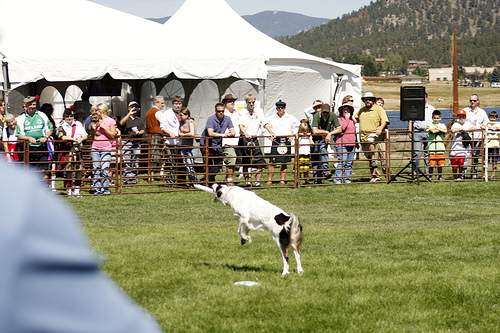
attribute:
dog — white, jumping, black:
[224, 186, 302, 262]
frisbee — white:
[195, 184, 219, 194]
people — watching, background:
[55, 91, 203, 125]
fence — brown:
[111, 141, 164, 198]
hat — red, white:
[272, 97, 281, 107]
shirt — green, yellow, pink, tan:
[86, 131, 103, 142]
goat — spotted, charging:
[206, 186, 251, 228]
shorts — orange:
[429, 158, 446, 166]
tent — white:
[127, 5, 228, 66]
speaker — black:
[400, 83, 428, 118]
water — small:
[391, 120, 399, 128]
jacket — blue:
[211, 123, 222, 128]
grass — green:
[95, 213, 182, 259]